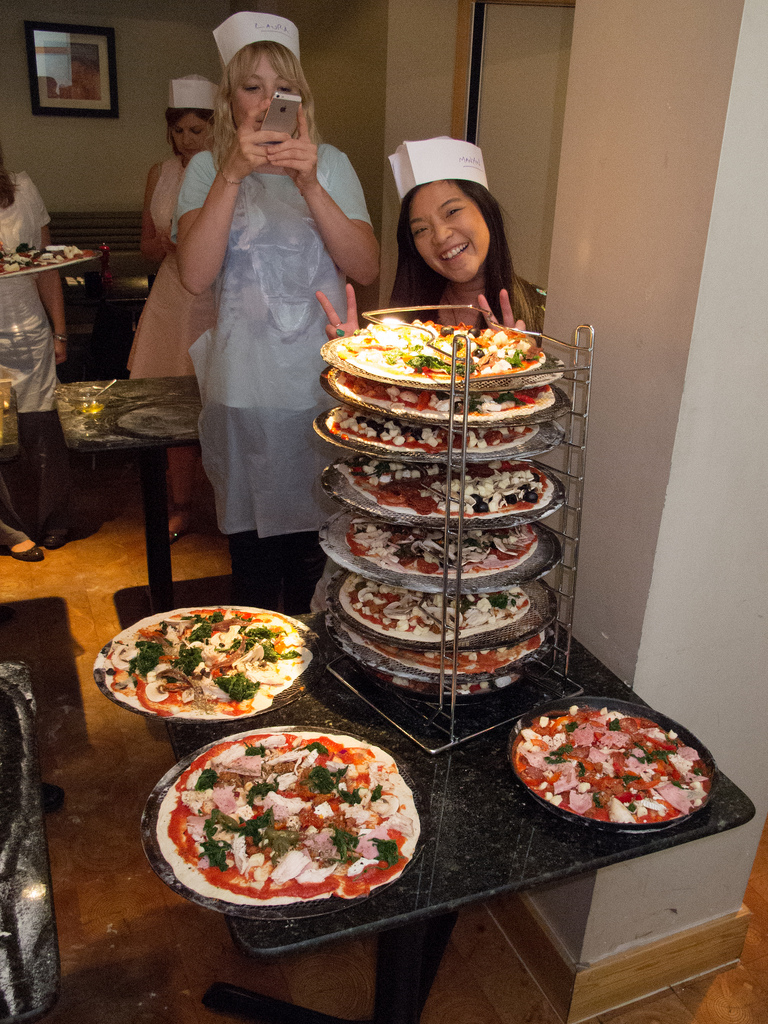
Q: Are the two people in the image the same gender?
A: Yes, all the people are female.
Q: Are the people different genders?
A: No, all the people are female.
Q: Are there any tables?
A: Yes, there is a table.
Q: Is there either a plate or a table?
A: Yes, there is a table.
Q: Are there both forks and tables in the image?
A: No, there is a table but no forks.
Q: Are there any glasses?
A: No, there are no glasses.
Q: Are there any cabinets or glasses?
A: No, there are no glasses or cabinets.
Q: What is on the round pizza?
A: The toppings are on the pizza.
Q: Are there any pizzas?
A: Yes, there is a pizza.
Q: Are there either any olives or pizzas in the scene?
A: Yes, there is a pizza.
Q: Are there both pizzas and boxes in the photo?
A: No, there is a pizza but no boxes.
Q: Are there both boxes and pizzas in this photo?
A: No, there is a pizza but no boxes.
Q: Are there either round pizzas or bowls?
A: Yes, there is a round pizza.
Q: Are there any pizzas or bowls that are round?
A: Yes, the pizza is round.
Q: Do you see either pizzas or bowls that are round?
A: Yes, the pizza is round.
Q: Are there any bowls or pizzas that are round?
A: Yes, the pizza is round.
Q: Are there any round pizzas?
A: Yes, there is a round pizza.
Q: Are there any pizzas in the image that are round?
A: Yes, there is a pizza that is round.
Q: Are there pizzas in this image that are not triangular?
A: Yes, there is a round pizza.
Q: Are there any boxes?
A: No, there are no boxes.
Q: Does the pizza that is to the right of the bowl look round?
A: Yes, the pizza is round.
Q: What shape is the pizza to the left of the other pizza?
A: The pizza is round.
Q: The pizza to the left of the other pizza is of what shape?
A: The pizza is round.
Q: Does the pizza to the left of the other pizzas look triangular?
A: No, the pizza is round.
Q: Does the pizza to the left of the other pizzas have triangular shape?
A: No, the pizza is round.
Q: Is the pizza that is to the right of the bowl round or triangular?
A: The pizza is round.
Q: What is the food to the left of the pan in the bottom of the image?
A: The food is a pizza.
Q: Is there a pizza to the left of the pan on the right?
A: Yes, there is a pizza to the left of the pan.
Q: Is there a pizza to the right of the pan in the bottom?
A: No, the pizza is to the left of the pan.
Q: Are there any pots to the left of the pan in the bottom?
A: No, there is a pizza to the left of the pan.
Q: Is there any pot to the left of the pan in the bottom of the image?
A: No, there is a pizza to the left of the pan.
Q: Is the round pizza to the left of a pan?
A: Yes, the pizza is to the left of a pan.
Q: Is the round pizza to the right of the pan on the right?
A: No, the pizza is to the left of the pan.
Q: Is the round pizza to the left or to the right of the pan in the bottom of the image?
A: The pizza is to the left of the pan.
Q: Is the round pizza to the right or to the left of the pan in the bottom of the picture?
A: The pizza is to the left of the pan.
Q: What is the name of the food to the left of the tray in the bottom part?
A: The food is a pizza.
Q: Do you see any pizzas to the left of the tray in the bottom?
A: Yes, there is a pizza to the left of the tray.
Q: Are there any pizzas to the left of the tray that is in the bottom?
A: Yes, there is a pizza to the left of the tray.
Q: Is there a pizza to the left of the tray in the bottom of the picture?
A: Yes, there is a pizza to the left of the tray.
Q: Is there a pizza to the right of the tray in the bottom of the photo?
A: No, the pizza is to the left of the tray.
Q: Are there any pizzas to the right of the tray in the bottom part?
A: No, the pizza is to the left of the tray.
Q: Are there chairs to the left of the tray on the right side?
A: No, there is a pizza to the left of the tray.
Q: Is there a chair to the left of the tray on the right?
A: No, there is a pizza to the left of the tray.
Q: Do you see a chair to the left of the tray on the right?
A: No, there is a pizza to the left of the tray.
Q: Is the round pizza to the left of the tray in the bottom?
A: Yes, the pizza is to the left of the tray.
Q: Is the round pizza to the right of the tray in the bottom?
A: No, the pizza is to the left of the tray.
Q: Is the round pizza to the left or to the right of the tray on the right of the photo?
A: The pizza is to the left of the tray.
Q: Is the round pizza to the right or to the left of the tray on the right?
A: The pizza is to the left of the tray.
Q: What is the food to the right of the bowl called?
A: The food is a pizza.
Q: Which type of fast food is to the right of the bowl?
A: The food is a pizza.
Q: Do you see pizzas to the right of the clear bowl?
A: Yes, there is a pizza to the right of the bowl.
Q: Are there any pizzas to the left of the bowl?
A: No, the pizza is to the right of the bowl.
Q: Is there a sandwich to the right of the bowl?
A: No, there is a pizza to the right of the bowl.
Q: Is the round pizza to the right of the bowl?
A: Yes, the pizza is to the right of the bowl.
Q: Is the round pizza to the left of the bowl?
A: No, the pizza is to the right of the bowl.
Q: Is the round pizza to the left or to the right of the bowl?
A: The pizza is to the right of the bowl.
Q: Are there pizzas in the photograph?
A: Yes, there is a pizza.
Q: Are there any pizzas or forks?
A: Yes, there is a pizza.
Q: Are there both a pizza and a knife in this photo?
A: No, there is a pizza but no knives.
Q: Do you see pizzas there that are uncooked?
A: Yes, there is a pizza that is uncooked.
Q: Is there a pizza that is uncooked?
A: Yes, there is a pizza that is uncooked.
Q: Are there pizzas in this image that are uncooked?
A: Yes, there is a pizza that is uncooked.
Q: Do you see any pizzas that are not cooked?
A: Yes, there is a uncooked pizza.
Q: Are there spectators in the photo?
A: No, there are no spectators.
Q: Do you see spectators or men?
A: No, there are no spectators or men.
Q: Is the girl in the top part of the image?
A: Yes, the girl is in the top of the image.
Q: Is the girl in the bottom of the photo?
A: No, the girl is in the top of the image.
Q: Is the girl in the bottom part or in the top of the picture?
A: The girl is in the top of the image.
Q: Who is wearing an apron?
A: The girl is wearing an apron.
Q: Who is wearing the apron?
A: The girl is wearing an apron.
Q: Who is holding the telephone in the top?
A: The girl is holding the phone.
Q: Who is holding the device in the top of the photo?
A: The girl is holding the phone.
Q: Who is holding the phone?
A: The girl is holding the phone.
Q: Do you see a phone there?
A: Yes, there is a phone.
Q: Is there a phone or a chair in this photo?
A: Yes, there is a phone.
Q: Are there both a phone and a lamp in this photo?
A: No, there is a phone but no lamps.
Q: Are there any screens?
A: No, there are no screens.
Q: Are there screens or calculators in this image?
A: No, there are no screens or calculators.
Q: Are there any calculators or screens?
A: No, there are no screens or calculators.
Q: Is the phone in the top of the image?
A: Yes, the phone is in the top of the image.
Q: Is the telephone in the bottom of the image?
A: No, the telephone is in the top of the image.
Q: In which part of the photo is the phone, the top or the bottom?
A: The phone is in the top of the image.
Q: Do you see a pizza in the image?
A: Yes, there is a pizza.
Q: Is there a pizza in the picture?
A: Yes, there is a pizza.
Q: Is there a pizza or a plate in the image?
A: Yes, there is a pizza.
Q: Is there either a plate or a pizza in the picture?
A: Yes, there is a pizza.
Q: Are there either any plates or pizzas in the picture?
A: Yes, there is a pizza.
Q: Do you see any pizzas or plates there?
A: Yes, there is a pizza.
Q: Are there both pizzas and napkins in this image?
A: No, there is a pizza but no napkins.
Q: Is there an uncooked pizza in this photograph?
A: Yes, there is an uncooked pizza.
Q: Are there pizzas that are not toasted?
A: Yes, there is a uncooked pizza.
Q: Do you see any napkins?
A: No, there are no napkins.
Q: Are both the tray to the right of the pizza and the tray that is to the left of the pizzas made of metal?
A: Yes, both the tray and the tray are made of metal.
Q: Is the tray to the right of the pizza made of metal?
A: Yes, the tray is made of metal.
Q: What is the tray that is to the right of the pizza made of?
A: The tray is made of metal.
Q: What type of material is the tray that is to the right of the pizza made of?
A: The tray is made of metal.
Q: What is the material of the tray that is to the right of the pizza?
A: The tray is made of metal.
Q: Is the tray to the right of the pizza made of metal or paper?
A: The tray is made of metal.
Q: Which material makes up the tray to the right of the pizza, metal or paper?
A: The tray is made of metal.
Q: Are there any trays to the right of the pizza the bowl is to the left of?
A: Yes, there is a tray to the right of the pizza.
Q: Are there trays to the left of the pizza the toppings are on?
A: No, the tray is to the right of the pizza.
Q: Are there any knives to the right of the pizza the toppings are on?
A: No, there is a tray to the right of the pizza.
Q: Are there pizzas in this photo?
A: Yes, there is a pizza.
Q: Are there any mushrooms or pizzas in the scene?
A: Yes, there is a pizza.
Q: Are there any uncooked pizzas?
A: Yes, there is an uncooked pizza.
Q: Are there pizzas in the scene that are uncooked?
A: Yes, there is an uncooked pizza.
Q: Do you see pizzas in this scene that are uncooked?
A: Yes, there is a pizza that is uncooked.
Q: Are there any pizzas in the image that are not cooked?
A: Yes, there is a uncooked pizza.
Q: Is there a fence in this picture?
A: No, there are no fences.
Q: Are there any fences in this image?
A: No, there are no fences.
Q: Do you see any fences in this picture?
A: No, there are no fences.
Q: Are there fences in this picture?
A: No, there are no fences.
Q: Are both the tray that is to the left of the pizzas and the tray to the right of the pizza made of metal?
A: Yes, both the tray and the tray are made of metal.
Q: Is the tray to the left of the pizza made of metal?
A: Yes, the tray is made of metal.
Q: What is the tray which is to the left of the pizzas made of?
A: The tray is made of metal.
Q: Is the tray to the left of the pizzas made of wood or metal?
A: The tray is made of metal.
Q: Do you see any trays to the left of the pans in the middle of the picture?
A: Yes, there is a tray to the left of the pans.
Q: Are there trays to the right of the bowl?
A: Yes, there is a tray to the right of the bowl.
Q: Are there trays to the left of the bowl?
A: No, the tray is to the right of the bowl.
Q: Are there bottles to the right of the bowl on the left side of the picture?
A: No, there is a tray to the right of the bowl.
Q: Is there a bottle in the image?
A: No, there are no bottles.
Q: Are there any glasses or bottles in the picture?
A: No, there are no bottles or glasses.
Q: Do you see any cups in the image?
A: No, there are no cups.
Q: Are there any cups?
A: No, there are no cups.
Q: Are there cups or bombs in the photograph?
A: No, there are no cups or bombs.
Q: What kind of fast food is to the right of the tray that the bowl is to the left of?
A: The food is pizzas.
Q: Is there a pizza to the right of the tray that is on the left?
A: Yes, there are pizzas to the right of the tray.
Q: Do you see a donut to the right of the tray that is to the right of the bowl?
A: No, there are pizzas to the right of the tray.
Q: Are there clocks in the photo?
A: No, there are no clocks.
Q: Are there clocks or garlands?
A: No, there are no clocks or garlands.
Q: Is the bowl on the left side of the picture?
A: Yes, the bowl is on the left of the image.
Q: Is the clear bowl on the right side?
A: No, the bowl is on the left of the image.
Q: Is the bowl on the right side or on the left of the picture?
A: The bowl is on the left of the image.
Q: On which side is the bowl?
A: The bowl is on the left of the image.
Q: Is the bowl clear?
A: Yes, the bowl is clear.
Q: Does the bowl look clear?
A: Yes, the bowl is clear.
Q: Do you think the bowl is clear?
A: Yes, the bowl is clear.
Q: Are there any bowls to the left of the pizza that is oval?
A: Yes, there is a bowl to the left of the pizza.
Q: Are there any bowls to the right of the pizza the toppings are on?
A: No, the bowl is to the left of the pizza.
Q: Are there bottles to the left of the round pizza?
A: No, there is a bowl to the left of the pizza.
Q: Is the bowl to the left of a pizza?
A: Yes, the bowl is to the left of a pizza.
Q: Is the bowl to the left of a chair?
A: No, the bowl is to the left of a pizza.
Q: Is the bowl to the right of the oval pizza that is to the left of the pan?
A: No, the bowl is to the left of the pizza.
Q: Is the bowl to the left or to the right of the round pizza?
A: The bowl is to the left of the pizza.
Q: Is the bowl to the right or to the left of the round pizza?
A: The bowl is to the left of the pizza.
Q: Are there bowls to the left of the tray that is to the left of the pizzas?
A: Yes, there is a bowl to the left of the tray.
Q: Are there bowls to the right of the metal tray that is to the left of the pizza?
A: No, the bowl is to the left of the tray.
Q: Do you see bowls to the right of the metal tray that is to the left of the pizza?
A: No, the bowl is to the left of the tray.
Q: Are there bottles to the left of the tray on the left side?
A: No, there is a bowl to the left of the tray.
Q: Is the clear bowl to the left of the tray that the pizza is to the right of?
A: Yes, the bowl is to the left of the tray.